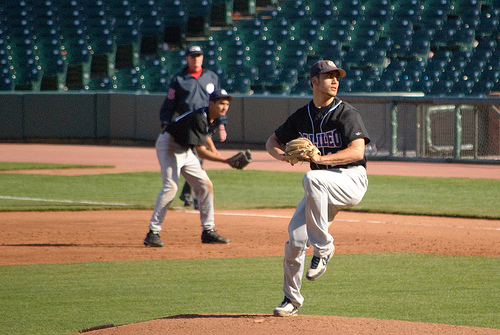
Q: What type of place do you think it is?
A: It is a field.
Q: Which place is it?
A: It is a field.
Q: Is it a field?
A: Yes, it is a field.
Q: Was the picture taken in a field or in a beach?
A: It was taken at a field.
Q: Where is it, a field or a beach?
A: It is a field.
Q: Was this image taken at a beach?
A: No, the picture was taken in a field.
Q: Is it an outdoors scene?
A: Yes, it is outdoors.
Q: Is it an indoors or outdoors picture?
A: It is outdoors.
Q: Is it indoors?
A: No, it is outdoors.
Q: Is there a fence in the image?
A: Yes, there is a fence.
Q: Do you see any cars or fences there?
A: Yes, there is a fence.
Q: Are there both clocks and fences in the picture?
A: No, there is a fence but no clocks.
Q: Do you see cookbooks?
A: No, there are no cookbooks.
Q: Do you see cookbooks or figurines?
A: No, there are no cookbooks or figurines.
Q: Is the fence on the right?
A: Yes, the fence is on the right of the image.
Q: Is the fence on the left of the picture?
A: No, the fence is on the right of the image.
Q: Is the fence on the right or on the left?
A: The fence is on the right of the image.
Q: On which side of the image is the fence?
A: The fence is on the right of the image.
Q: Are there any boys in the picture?
A: No, there are no boys.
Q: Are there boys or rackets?
A: No, there are no boys or rackets.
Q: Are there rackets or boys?
A: No, there are no boys or rackets.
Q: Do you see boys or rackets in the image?
A: No, there are no boys or rackets.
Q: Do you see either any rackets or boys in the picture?
A: No, there are no boys or rackets.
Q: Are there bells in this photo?
A: No, there are no bells.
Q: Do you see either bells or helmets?
A: No, there are no bells or helmets.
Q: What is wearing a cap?
A: The pitcher is wearing a cap.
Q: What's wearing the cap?
A: The pitcher is wearing a cap.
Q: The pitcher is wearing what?
A: The pitcher is wearing a cap.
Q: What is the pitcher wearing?
A: The pitcher is wearing a cap.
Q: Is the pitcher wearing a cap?
A: Yes, the pitcher is wearing a cap.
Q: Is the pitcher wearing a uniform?
A: No, the pitcher is wearing a cap.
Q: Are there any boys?
A: No, there are no boys.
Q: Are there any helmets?
A: No, there are no helmets.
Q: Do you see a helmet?
A: No, there are no helmets.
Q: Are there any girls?
A: No, there are no girls.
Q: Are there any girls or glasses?
A: No, there are no girls or glasses.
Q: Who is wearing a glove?
A: The catcher is wearing a glove.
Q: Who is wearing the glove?
A: The catcher is wearing a glove.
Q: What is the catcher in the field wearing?
A: The catcher is wearing a glove.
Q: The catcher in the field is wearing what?
A: The catcher is wearing a glove.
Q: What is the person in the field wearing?
A: The catcher is wearing a glove.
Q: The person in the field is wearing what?
A: The catcher is wearing a glove.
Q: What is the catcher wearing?
A: The catcher is wearing a glove.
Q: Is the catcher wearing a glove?
A: Yes, the catcher is wearing a glove.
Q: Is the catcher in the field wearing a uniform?
A: No, the catcher is wearing a glove.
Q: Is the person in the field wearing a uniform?
A: No, the catcher is wearing a glove.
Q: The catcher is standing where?
A: The catcher is standing on the field.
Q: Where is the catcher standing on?
A: The catcher is standing on the field.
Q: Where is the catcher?
A: The catcher is in the field.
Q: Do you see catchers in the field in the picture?
A: Yes, there is a catcher in the field.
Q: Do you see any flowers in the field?
A: No, there is a catcher in the field.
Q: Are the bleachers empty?
A: Yes, the bleachers are empty.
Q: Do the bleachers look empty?
A: Yes, the bleachers are empty.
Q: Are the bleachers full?
A: No, the bleachers are empty.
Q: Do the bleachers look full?
A: No, the bleachers are empty.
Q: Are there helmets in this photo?
A: No, there are no helmets.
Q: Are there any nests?
A: No, there are no nests.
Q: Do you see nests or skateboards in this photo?
A: No, there are no nests or skateboards.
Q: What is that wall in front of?
A: The wall is in front of the bleachers.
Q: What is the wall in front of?
A: The wall is in front of the bleachers.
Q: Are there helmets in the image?
A: No, there are no helmets.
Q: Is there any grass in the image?
A: Yes, there is grass.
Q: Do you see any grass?
A: Yes, there is grass.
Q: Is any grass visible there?
A: Yes, there is grass.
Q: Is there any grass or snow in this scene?
A: Yes, there is grass.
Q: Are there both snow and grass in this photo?
A: No, there is grass but no snow.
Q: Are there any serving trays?
A: No, there are no serving trays.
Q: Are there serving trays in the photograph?
A: No, there are no serving trays.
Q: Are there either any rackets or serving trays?
A: No, there are no serving trays or rackets.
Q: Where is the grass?
A: The grass is on the field.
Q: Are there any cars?
A: No, there are no cars.